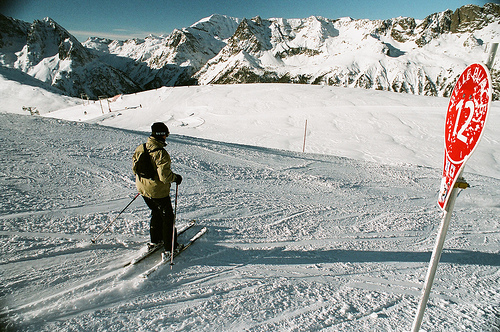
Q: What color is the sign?
A: Red.